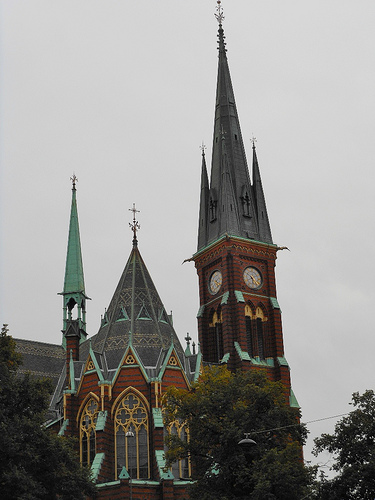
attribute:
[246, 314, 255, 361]
window — clear, gold, arched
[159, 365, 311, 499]
tree top — green, on the right, yellowing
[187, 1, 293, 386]
tower — the tallest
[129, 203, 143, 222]
cross — gray, on top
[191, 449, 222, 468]
branch — brown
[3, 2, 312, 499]
building — teal, large, pointy, brick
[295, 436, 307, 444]
leaf — green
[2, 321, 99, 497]
tree — in front, on the left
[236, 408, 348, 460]
power line — hanging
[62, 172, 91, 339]
spire — on the left, narrow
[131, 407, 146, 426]
circle — yellow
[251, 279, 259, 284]
hand — gold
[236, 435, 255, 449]
lamp — dark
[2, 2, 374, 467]
sky — overcast